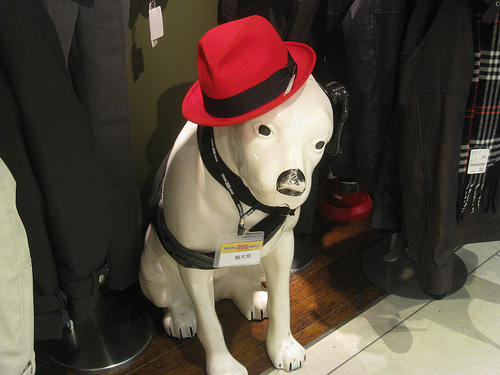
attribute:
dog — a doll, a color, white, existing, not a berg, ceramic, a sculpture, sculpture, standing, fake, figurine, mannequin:
[137, 75, 335, 369]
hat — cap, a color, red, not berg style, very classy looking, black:
[181, 14, 317, 129]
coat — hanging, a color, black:
[6, 5, 115, 340]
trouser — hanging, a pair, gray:
[67, 5, 143, 291]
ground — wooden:
[30, 217, 495, 370]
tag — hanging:
[213, 232, 265, 269]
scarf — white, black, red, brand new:
[456, 9, 496, 224]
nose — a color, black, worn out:
[276, 168, 309, 195]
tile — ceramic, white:
[273, 241, 495, 369]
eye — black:
[254, 121, 274, 140]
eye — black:
[312, 136, 327, 153]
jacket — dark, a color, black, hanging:
[394, 4, 476, 298]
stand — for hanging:
[359, 230, 470, 299]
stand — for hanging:
[37, 290, 157, 369]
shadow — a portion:
[183, 209, 223, 253]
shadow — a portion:
[336, 250, 496, 352]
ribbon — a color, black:
[205, 52, 300, 120]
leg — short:
[178, 264, 230, 359]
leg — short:
[266, 230, 295, 333]